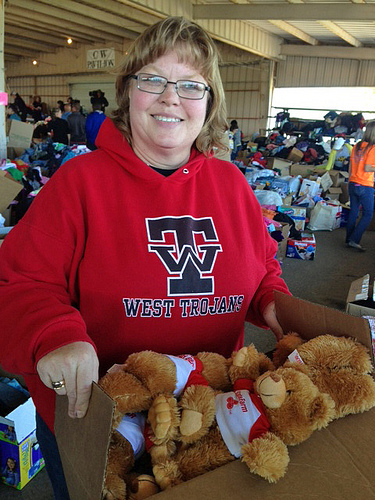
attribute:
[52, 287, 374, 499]
box — cardboard, large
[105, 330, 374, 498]
teddy bears — brown, plush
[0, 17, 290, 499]
woman — smiling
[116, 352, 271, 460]
shirts — red, white, state farm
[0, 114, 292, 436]
sweatshirt — red, west trojans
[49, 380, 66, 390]
ring — gold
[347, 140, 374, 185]
shirt — orange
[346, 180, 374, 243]
jeans — blue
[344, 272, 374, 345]
box — empty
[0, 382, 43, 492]
box — empty, yellow, cardboard, blue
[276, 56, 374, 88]
door — open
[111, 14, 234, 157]
hair — blond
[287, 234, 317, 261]
box — red, blue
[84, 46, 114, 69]
sign — black, white